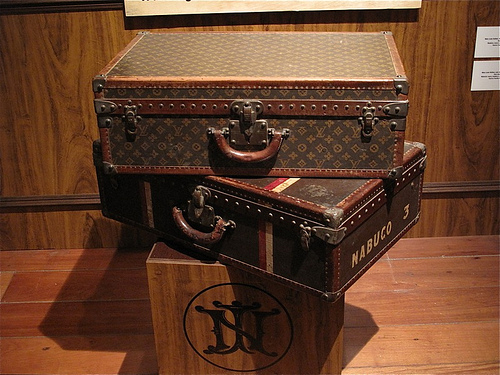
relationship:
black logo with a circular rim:
[179, 283, 294, 373] [180, 281, 292, 373]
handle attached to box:
[207, 127, 291, 164] [65, 17, 435, 184]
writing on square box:
[181, 282, 295, 374] [147, 240, 345, 375]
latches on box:
[119, 97, 381, 139] [87, 25, 410, 182]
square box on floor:
[147, 255, 357, 372] [348, 287, 427, 372]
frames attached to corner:
[90, 32, 406, 90] [379, 73, 425, 123]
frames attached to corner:
[88, 74, 115, 126] [80, 72, 115, 115]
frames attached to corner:
[313, 202, 350, 242] [309, 195, 365, 239]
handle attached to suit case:
[207, 127, 291, 164] [114, 21, 409, 182]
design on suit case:
[77, 25, 411, 171] [118, 36, 339, 173]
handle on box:
[207, 127, 291, 164] [90, 31, 410, 178]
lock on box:
[226, 97, 269, 148] [90, 31, 410, 178]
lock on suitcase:
[184, 186, 215, 226] [89, 131, 434, 300]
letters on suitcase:
[351, 218, 401, 269] [89, 131, 434, 300]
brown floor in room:
[412, 239, 487, 363] [0, 0, 497, 372]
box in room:
[90, 31, 410, 178] [0, 0, 497, 372]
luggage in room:
[91, 139, 426, 303] [0, 0, 497, 372]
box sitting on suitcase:
[90, 31, 410, 178] [89, 131, 434, 300]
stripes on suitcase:
[263, 221, 274, 274] [45, 28, 425, 182]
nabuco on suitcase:
[351, 219, 393, 267] [89, 131, 434, 300]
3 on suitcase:
[393, 190, 424, 228] [71, 16, 436, 179]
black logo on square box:
[183, 283, 295, 372] [147, 240, 345, 375]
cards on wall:
[461, 5, 496, 107] [1, 9, 498, 304]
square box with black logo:
[147, 240, 345, 375] [183, 283, 295, 372]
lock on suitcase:
[184, 186, 215, 232] [89, 139, 427, 309]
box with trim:
[90, 31, 410, 178] [383, 29, 413, 184]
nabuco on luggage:
[351, 217, 397, 272] [89, 28, 429, 305]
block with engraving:
[143, 257, 344, 367] [177, 280, 296, 372]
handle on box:
[199, 121, 294, 168] [90, 31, 410, 178]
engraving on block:
[177, 280, 296, 372] [146, 238, 343, 373]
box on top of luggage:
[87, 25, 410, 182] [91, 139, 426, 303]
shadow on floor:
[44, 225, 372, 373] [4, 238, 479, 373]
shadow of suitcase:
[44, 225, 372, 373] [249, 128, 351, 224]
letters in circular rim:
[194, 290, 284, 363] [183, 281, 294, 370]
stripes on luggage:
[246, 170, 315, 280] [92, 135, 426, 302]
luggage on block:
[98, 132, 444, 306] [138, 225, 358, 373]